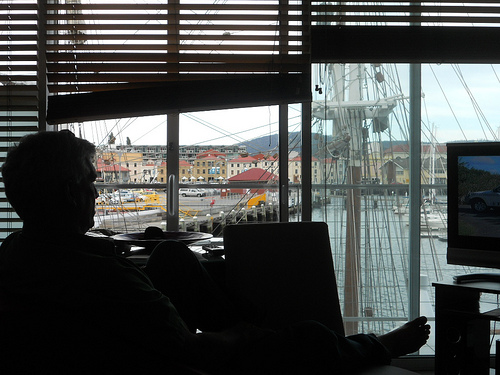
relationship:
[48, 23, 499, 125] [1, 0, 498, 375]
blinds on window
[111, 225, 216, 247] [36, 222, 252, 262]
bowl on table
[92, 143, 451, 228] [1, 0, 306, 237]
building outside window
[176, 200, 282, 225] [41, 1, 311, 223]
bridge outside window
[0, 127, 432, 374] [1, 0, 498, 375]
man outside window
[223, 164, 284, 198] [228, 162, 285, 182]
building with top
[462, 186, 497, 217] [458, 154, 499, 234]
automobile with monitor screen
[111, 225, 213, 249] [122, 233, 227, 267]
bowl on table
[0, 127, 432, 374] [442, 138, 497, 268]
man watching telelvision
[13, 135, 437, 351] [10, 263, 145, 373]
man relaxing in chair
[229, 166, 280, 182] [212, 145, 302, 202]
top of building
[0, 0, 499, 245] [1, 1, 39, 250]
blinds on window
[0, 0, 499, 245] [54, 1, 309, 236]
blinds on window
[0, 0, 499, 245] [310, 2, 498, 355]
blinds on window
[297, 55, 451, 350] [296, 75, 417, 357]
sail from boat